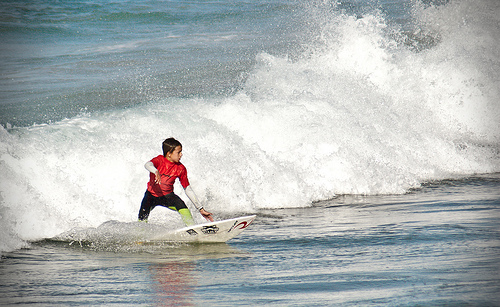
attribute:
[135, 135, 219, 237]
boy — young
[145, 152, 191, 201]
shirt — red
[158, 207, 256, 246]
surfboard — white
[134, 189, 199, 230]
pants — black, green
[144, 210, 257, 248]
surfboard — white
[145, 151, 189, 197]
shirt — red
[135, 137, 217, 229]
surfer — young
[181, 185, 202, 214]
sleeve — White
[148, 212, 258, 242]
surfboard — White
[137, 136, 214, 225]
surfboard — white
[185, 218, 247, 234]
design — black, red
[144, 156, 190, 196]
shirt — red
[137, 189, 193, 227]
pants — Black, green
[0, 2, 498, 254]
ocean wave — White, foamy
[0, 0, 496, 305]
water — blue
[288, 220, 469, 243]
ripples — big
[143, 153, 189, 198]
swim suit — red